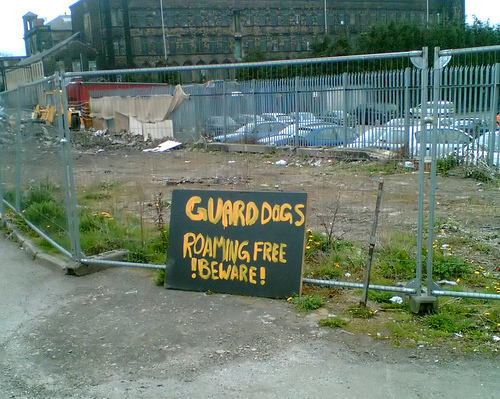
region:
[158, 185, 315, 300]
a black sign on the sidewalk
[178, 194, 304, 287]
yellow writing on the sign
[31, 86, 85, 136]
a yellow piece of heavy machinery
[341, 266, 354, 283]
a small white flower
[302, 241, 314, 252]
a small yellow flower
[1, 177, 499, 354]
a patch of green grass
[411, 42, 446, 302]
metal fence posts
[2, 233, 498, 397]
a gray gravel and cement sidewalk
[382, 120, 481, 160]
a gray car in the lot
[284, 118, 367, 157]
a black car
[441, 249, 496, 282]
the flowers are yellow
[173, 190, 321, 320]
the sign is yellow and black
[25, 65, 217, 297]
the metal fence is tall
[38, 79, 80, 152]
the tractor is yellow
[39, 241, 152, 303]
fence is sitting on cinder blocks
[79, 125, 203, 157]
there is trash in the fenced area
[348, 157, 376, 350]
a metal pole leaning on the fence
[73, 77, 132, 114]
the building is red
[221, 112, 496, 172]
vehicles parked on other side of fence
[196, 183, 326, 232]
GUARD DOGS is written on the sign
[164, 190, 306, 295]
black sign on the ground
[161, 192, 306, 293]
black sign with yellow writing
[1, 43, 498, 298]
gray, metal fence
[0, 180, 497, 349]
line of patch of grass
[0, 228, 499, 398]
area of concrete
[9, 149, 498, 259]
area of dirt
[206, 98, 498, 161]
group of cars behind fence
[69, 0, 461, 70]
large, brick building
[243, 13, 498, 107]
group of trees behind cars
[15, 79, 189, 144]
group of trash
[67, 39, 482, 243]
the fence is silver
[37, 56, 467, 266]
the fence is made of metal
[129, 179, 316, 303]
the sign is green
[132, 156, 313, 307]
the letters are written in yellow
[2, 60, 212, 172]
the area has garbage in it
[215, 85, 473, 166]
the cars are parked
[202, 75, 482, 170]
cars are behind the fence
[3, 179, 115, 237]
little yellow flowers are growing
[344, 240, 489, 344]
grass is growing in the dirt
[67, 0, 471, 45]
the building is dark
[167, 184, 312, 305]
A hand written sign warning of guard dogs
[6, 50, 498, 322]
A metal fence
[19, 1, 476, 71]
A building in the background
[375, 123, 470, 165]
Part of a car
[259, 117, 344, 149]
Part of a car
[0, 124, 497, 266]
A large dirt area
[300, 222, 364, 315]
Some dandelions and grass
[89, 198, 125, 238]
Some dandelions and glass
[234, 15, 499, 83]
The tops of some trees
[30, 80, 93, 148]
A piece of heavy machinery